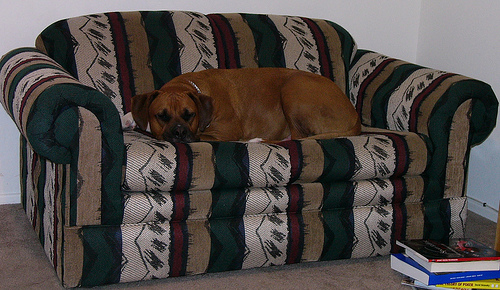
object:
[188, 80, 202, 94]
collar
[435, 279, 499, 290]
book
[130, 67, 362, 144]
bullmastiff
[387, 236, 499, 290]
stack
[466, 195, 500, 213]
wire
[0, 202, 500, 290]
floor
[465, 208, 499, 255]
carpet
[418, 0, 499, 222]
wall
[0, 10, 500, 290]
couch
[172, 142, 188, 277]
stripe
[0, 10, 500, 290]
love seat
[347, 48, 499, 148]
arm rest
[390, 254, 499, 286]
blue book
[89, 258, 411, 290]
carpet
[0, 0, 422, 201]
white wall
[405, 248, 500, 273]
books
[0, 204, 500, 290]
ground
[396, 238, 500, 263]
book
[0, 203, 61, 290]
carpet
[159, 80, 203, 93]
neck